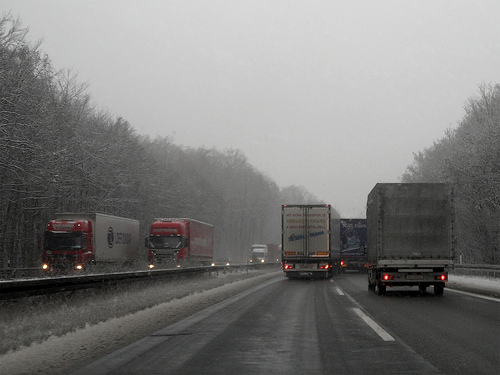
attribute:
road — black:
[219, 305, 397, 359]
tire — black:
[376, 277, 387, 293]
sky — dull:
[243, 48, 393, 125]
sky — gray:
[144, 8, 402, 133]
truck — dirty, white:
[367, 180, 463, 296]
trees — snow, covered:
[7, 42, 272, 243]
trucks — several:
[33, 179, 458, 300]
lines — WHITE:
[347, 300, 389, 345]